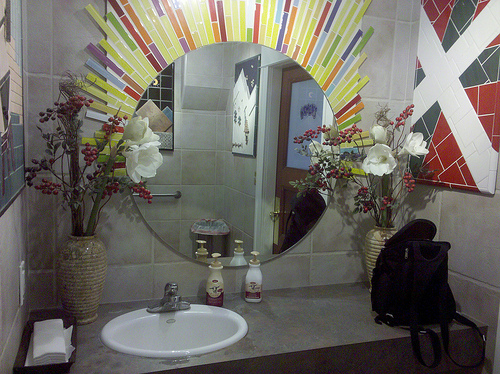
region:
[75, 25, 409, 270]
The mirror is round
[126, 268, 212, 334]
The sink is off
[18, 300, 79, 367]
The paper towels are white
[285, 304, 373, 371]
The counter top is gray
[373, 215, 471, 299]
The bag is open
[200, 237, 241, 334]
The soap is a pump bottle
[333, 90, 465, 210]
The flowers are white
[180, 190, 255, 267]
The trash can is in the mirror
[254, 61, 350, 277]
The door is shut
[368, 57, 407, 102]
The wall is light colored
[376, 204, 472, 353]
the black color bag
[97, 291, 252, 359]
the white color basin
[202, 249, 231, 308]
the hand washer in the cream color bottle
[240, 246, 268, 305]
the hand washer in white color bottle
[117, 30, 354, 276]
the mirror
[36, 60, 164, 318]
the flower was near the basin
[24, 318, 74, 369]
the white color tissue papers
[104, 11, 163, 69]
the stickers on the mirror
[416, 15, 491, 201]
the design on the tiles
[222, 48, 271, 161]
the photo frame in the mirror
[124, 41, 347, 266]
Bathroom mirror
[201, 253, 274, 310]
Hand washing soap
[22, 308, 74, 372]
Napkins for washing hands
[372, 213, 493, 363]
Black back pack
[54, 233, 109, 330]
Decorative bathroom Vace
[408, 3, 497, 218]
Decorative Red White and Gray Wall tile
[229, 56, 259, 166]
Reflection of wall decorations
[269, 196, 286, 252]
Reflection of a brass door handle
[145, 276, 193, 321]
Chrome hand washing faucet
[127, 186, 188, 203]
rack for holding towells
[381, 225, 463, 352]
Black bag on counter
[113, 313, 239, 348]
White sink in bathroom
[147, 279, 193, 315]
Silver faucet on sink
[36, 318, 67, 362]
White paper towel in holder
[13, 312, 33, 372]
Burgandy paper towel holder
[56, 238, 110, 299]
Brownish tannish vase on counter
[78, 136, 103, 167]
Red cherries in vase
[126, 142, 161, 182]
White flowers in vase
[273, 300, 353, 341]
Silver granite bathroom counter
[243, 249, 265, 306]
White bottle of lotion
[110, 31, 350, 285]
round mirror on wall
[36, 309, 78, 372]
stack of white paper towels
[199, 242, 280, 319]
two bottles on vanity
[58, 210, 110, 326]
green stems in vase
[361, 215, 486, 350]
black bag on counter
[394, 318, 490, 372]
two straps of bag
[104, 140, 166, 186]
large white flower on stem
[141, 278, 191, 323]
faucet over white sink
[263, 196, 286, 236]
brass handle on door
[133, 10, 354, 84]
colorful decoration above morror